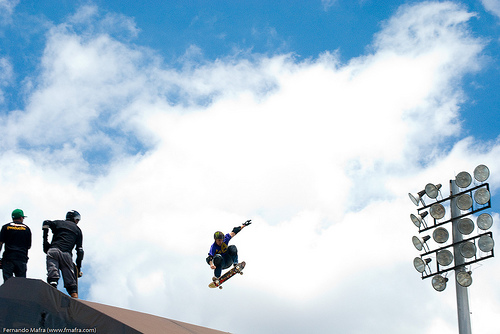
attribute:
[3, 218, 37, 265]
shirt — black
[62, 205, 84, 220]
helmet — black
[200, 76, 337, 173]
clouds — white, large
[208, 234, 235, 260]
shirt — blue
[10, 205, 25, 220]
cap — green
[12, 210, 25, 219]
hat — green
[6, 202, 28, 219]
hat — green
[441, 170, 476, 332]
pole — metal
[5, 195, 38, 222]
cap — blue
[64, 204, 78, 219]
helmet — black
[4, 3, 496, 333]
sky — blue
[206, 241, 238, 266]
t-shirt — blue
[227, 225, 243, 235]
elbow pad — black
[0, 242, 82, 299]
pants — grey